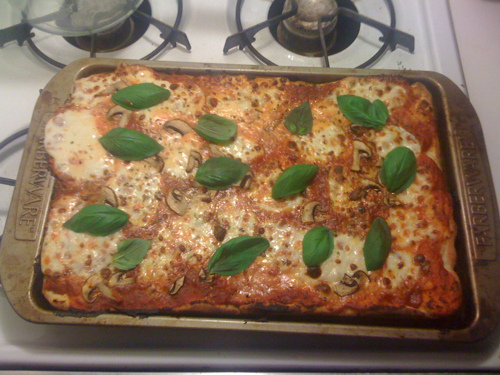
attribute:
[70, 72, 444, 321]
pizza — white, cheesy, yellow, red, homemade, cheesey, burnt, done, hot, small, cooked, overcooked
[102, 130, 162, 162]
leaf — green, on pizza, fresh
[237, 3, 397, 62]
burner — black, metal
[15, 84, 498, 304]
pan — metal, gold, small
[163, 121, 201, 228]
mushrooms — white, grey